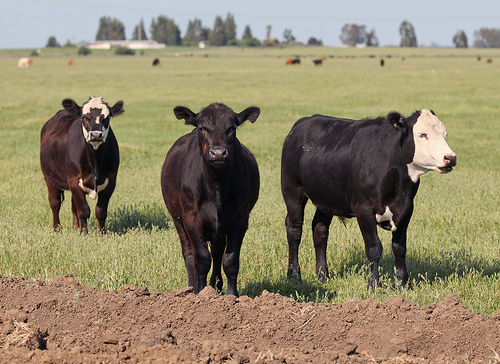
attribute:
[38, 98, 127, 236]
cow — standing, hereford, posing, mean looking, dark brown, black, white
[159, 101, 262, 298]
cow — standing, angus, looking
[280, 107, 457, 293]
cow — standing, hereford, cowpacetic, black, white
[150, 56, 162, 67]
cow — distant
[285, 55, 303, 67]
cow — distant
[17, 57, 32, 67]
cow — distant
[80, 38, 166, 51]
building — low, white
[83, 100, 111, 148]
face — white, brown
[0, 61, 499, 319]
field — green, grassy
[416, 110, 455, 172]
face — white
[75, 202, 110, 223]
knees — odd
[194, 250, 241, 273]
knees — odd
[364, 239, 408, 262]
knees — odd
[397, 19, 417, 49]
tree — tall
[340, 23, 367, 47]
tree — tall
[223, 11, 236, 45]
tree — tall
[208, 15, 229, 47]
tree — tall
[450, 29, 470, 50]
tree — tall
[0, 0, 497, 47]
sky — blue